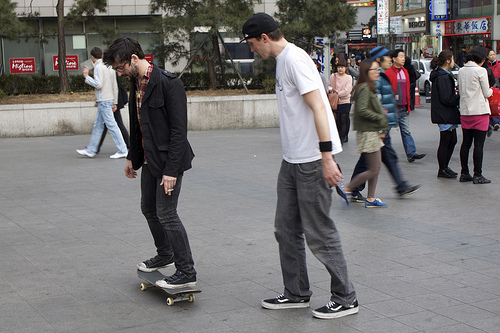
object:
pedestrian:
[427, 46, 461, 178]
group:
[423, 44, 495, 185]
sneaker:
[309, 300, 360, 321]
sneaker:
[259, 293, 312, 310]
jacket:
[124, 61, 196, 177]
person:
[75, 48, 130, 159]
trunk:
[54, 0, 72, 94]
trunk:
[205, 25, 221, 90]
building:
[0, 0, 284, 77]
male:
[102, 36, 201, 292]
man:
[382, 47, 428, 162]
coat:
[382, 64, 411, 115]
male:
[235, 10, 360, 322]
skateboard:
[135, 268, 203, 307]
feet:
[155, 269, 200, 288]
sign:
[440, 16, 490, 36]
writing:
[453, 20, 490, 35]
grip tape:
[137, 265, 204, 295]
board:
[135, 267, 202, 296]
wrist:
[319, 148, 333, 157]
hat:
[232, 11, 284, 46]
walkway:
[0, 108, 499, 332]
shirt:
[269, 40, 342, 164]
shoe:
[154, 267, 196, 290]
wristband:
[316, 140, 334, 153]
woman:
[455, 46, 493, 184]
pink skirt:
[458, 115, 489, 132]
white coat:
[455, 60, 493, 117]